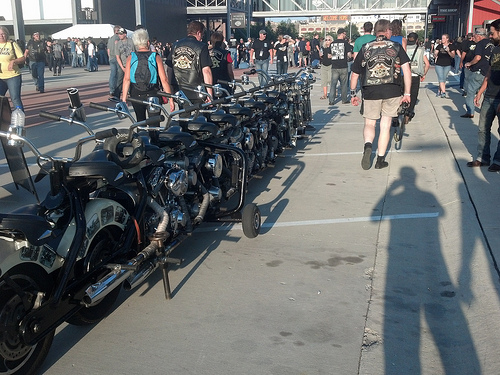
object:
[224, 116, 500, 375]
sidewalk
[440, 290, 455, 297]
stain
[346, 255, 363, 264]
stain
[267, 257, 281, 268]
stain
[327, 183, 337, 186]
stain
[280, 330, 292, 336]
stain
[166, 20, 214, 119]
man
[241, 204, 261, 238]
wheel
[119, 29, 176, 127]
woman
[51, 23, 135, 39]
tent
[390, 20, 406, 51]
person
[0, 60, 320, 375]
bikes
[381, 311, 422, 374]
leg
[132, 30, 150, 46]
silver hair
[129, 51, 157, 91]
vest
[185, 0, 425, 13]
walkway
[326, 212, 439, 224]
line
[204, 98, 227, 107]
handles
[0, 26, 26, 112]
woman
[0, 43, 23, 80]
t-shirt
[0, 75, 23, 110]
jeans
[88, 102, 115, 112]
handles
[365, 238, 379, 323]
line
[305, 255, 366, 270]
mark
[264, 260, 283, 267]
mark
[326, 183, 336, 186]
mark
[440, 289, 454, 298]
mark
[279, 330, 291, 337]
mark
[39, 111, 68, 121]
handles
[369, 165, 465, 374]
shadow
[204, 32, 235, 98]
man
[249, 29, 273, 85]
man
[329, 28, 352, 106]
man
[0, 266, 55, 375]
wheel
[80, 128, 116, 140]
handles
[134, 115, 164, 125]
handles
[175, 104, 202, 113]
handles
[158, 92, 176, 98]
handles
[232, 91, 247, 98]
handles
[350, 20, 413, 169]
man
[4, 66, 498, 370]
ground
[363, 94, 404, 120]
shorts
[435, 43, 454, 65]
t-shirt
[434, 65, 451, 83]
capris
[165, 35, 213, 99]
jacket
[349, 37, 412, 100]
shirt